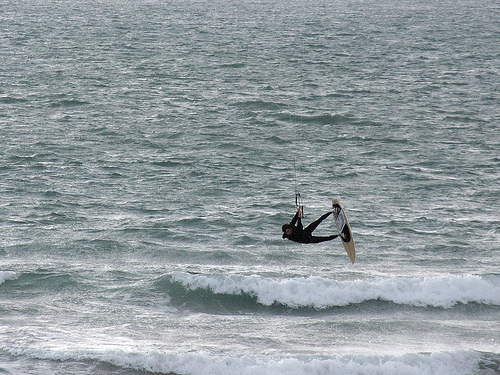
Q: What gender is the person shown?
A: Male.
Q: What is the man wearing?
A: Wetsuit.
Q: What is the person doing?
A: Kitesurfing.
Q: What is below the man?
A: Wave.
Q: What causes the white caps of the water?
A: Wave.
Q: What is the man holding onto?
A: Kite string.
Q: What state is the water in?
A: Wavy.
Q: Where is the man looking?
A: At the water.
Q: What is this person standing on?
A: Wakeboard.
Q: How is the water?
A: Foamy.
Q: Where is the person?
A: In air.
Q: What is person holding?
A: A handle.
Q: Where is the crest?
A: Of wave.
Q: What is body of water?
A: Ocean.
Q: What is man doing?
A: Kitesurfing.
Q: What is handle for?
A: Kite.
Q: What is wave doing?
A: Crashing.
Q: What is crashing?
A: Wave.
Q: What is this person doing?
A: Windsurfing.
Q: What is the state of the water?
A: Choppy.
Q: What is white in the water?
A: The waves.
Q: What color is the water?
A: Blue.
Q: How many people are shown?
A: 1.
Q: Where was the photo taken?
A: The beach.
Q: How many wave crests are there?
A: 2.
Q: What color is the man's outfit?
A: Black.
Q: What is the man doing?
A: Wakeboarding.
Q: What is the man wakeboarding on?
A: Water.